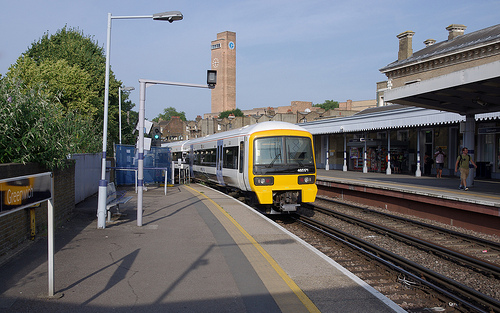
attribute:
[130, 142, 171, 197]
fence — blue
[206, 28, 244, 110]
building — tall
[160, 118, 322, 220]
train — yellow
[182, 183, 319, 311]
line — yellow, painted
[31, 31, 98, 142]
tree — large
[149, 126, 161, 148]
light — night light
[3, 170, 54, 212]
sign — black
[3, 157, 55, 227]
sign — black, yellow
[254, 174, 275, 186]
light — black, silver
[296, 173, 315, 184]
light — black, silver